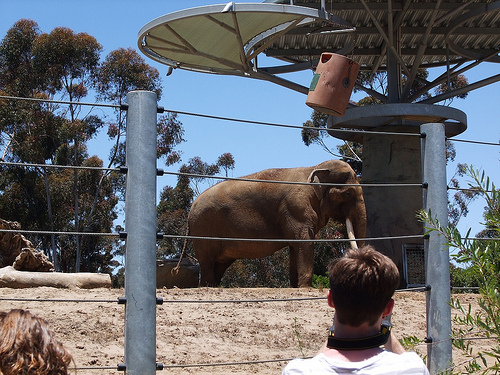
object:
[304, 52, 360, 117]
feeding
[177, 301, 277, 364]
ground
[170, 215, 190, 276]
tail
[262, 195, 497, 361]
compound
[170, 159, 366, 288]
elephant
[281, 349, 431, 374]
t-shirt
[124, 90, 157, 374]
pole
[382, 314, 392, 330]
recording device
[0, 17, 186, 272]
tree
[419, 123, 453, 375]
pole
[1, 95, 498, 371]
wires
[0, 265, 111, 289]
trunk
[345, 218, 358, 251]
tusk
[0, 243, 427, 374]
people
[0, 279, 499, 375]
dirt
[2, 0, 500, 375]
zoo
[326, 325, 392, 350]
strap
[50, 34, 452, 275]
wild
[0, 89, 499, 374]
enclosure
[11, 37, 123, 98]
leaves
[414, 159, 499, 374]
vegetation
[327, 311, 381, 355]
neck